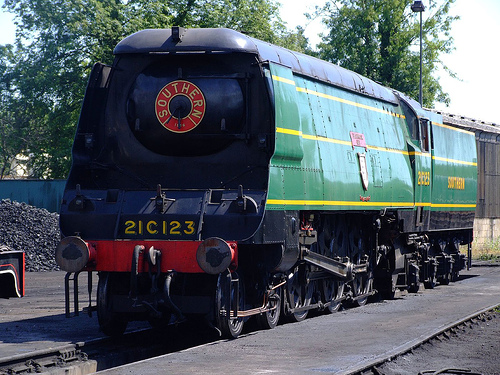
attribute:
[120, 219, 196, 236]
numbers — yellow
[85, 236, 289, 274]
bumper — red, black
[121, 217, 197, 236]
letters numbers — yellow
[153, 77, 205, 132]
circle — yellow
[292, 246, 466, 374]
ground — smooth, grey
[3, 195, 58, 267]
rocks — piled, grey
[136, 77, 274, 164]
writing — yellow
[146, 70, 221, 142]
circle logo — red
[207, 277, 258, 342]
wheel — black, round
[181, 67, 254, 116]
wall — black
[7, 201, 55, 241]
rocks — piled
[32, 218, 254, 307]
metal bumper — black, red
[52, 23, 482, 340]
train — green, parked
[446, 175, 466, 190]
writing — yellow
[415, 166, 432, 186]
writing — yellow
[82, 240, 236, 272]
stripe — red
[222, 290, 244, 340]
wheel — black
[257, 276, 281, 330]
wheel — black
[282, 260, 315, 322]
wheel — black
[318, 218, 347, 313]
wheel — black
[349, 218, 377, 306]
wheel — black